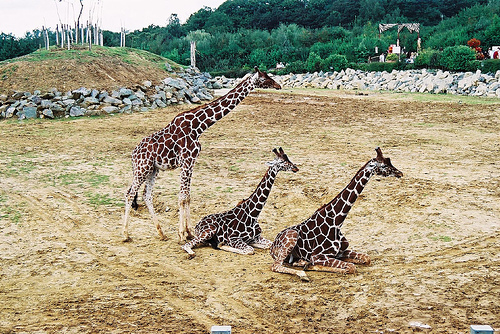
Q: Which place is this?
A: It is a pen.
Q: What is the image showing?
A: It is showing a pen.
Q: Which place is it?
A: It is a pen.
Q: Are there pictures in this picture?
A: No, there are no pictures.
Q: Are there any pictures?
A: No, there are no pictures.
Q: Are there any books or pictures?
A: No, there are no pictures or books.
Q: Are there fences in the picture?
A: No, there are no fences.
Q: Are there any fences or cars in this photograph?
A: No, there are no fences or cars.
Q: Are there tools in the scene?
A: No, there are no tools.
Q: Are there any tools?
A: No, there are no tools.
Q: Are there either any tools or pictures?
A: No, there are no tools or pictures.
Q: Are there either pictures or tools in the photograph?
A: No, there are no tools or pictures.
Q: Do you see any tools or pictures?
A: No, there are no tools or pictures.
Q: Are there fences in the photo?
A: No, there are no fences.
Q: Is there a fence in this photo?
A: No, there are no fences.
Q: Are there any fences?
A: No, there are no fences.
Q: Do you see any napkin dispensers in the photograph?
A: No, there are no napkin dispensers.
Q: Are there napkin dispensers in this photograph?
A: No, there are no napkin dispensers.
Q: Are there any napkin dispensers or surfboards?
A: No, there are no napkin dispensers or surfboards.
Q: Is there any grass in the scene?
A: Yes, there is grass.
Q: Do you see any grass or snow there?
A: Yes, there is grass.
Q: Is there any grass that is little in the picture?
A: Yes, there is little grass.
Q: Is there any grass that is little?
A: Yes, there is grass that is little.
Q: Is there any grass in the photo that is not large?
A: Yes, there is little grass.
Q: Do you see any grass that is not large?
A: Yes, there is little grass.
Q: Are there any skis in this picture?
A: No, there are no skis.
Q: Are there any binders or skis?
A: No, there are no skis or binders.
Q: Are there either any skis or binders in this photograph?
A: No, there are no skis or binders.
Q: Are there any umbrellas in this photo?
A: No, there are no umbrellas.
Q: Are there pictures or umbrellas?
A: No, there are no umbrellas or pictures.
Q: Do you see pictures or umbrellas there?
A: No, there are no umbrellas or pictures.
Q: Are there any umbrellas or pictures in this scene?
A: No, there are no umbrellas or pictures.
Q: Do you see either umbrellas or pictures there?
A: No, there are no umbrellas or pictures.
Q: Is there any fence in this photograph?
A: No, there are no fences.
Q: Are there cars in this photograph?
A: No, there are no cars.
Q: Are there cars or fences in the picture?
A: No, there are no cars or fences.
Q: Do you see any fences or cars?
A: No, there are no cars or fences.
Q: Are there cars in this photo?
A: No, there are no cars.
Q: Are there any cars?
A: No, there are no cars.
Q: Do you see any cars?
A: No, there are no cars.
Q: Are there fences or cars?
A: No, there are no cars or fences.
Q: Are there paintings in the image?
A: No, there are no paintings.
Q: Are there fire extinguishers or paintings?
A: No, there are no paintings or fire extinguishers.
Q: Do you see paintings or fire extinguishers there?
A: No, there are no paintings or fire extinguishers.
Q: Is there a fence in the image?
A: No, there are no fences.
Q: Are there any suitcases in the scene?
A: No, there are no suitcases.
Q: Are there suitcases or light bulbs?
A: No, there are no suitcases or light bulbs.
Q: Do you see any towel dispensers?
A: No, there are no towel dispensers.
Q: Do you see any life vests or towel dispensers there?
A: No, there are no towel dispensers or life vests.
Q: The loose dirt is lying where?
A: The dirt is lying in the pen.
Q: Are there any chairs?
A: No, there are no chairs.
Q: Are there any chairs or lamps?
A: No, there are no chairs or lamps.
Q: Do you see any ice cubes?
A: No, there are no ice cubes.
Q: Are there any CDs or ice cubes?
A: No, there are no ice cubes or cds.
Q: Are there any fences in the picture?
A: No, there are no fences.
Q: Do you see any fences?
A: No, there are no fences.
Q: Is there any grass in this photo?
A: Yes, there is grass.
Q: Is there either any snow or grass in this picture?
A: Yes, there is grass.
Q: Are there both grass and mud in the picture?
A: No, there is grass but no mud.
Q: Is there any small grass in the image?
A: Yes, there is small grass.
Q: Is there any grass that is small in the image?
A: Yes, there is small grass.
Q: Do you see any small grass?
A: Yes, there is small grass.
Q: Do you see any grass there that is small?
A: Yes, there is grass that is small.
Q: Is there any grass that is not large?
A: Yes, there is small grass.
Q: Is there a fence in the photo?
A: No, there are no fences.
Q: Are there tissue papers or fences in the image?
A: No, there are no fences or tissue papers.